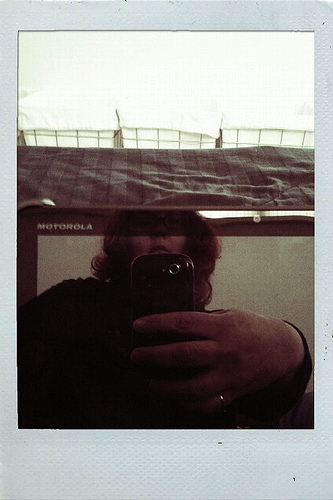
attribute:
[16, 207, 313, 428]
woman — reflected, photographing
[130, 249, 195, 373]
phone — black, silver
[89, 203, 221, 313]
hair — curly, short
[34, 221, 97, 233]
label — brand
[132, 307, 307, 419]
hand — reflected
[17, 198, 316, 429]
cellphone — held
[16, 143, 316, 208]
awning — striped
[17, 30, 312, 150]
sky — daytime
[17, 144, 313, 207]
drapes — covering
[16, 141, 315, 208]
blanket — striped